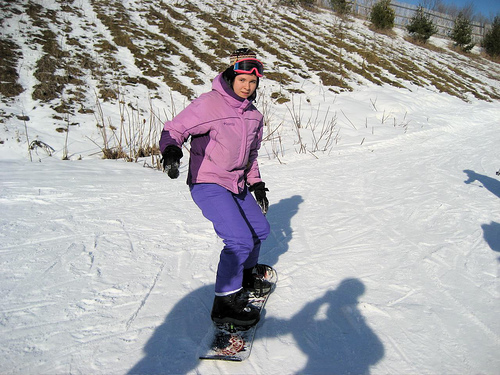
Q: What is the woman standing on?
A: Snowboard.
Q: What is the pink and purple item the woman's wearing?
A: Coat.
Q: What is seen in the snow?
A: Shadow.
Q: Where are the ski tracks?
A: In snow.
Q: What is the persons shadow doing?
A: Taking a picture.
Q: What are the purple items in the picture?
A: Pants.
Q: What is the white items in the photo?
A: Snow.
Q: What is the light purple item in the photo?
A: Jacket.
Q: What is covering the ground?
A: Snow.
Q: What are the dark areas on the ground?
A: Shadows.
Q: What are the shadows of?
A: Other people.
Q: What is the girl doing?
A: Snow boarding.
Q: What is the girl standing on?
A: Snow board.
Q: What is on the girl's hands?
A: Gloves.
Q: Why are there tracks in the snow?
A: Snowboard.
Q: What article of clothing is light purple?
A: Jacket.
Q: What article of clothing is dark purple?
A: Pants.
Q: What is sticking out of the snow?
A: Weeds.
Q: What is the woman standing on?
A: A snowboard.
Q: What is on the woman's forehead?
A: Goggles.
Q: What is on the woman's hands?
A: Black gloves.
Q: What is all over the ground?
A: Snow.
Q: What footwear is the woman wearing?
A: Boots.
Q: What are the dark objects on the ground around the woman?
A: Shadows.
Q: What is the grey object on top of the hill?
A: A fence.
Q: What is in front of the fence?
A: Trees.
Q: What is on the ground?
A: Snow.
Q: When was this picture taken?
A: Daytime.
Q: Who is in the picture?
A: A girl.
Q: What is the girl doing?
A: Snowboarding.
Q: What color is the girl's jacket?
A: Pink.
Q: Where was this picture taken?
A: A ski slope.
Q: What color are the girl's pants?
A: Blue.